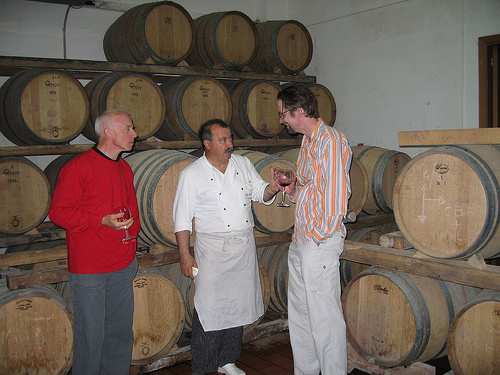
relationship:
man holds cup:
[46, 112, 146, 371] [108, 199, 137, 246]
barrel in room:
[102, 2, 197, 68] [2, 2, 499, 368]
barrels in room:
[189, 11, 259, 73] [2, 2, 499, 368]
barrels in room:
[250, 18, 316, 73] [2, 2, 499, 368]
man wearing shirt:
[46, 112, 146, 371] [49, 149, 139, 270]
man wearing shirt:
[175, 119, 269, 374] [172, 150, 275, 231]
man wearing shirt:
[275, 82, 354, 375] [278, 125, 360, 247]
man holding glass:
[275, 82, 354, 375] [272, 160, 295, 210]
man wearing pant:
[46, 112, 146, 371] [66, 253, 138, 374]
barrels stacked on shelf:
[95, 28, 316, 77] [4, 54, 345, 153]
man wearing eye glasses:
[275, 82, 354, 375] [277, 106, 305, 119]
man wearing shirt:
[175, 119, 269, 374] [170, 151, 277, 242]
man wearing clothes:
[175, 119, 269, 374] [172, 152, 271, 331]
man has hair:
[46, 112, 146, 371] [76, 90, 116, 144]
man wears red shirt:
[46, 104, 146, 371] [48, 149, 142, 275]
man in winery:
[275, 82, 354, 375] [1, 0, 499, 374]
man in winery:
[175, 119, 269, 374] [1, 0, 499, 374]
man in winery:
[46, 112, 146, 371] [1, 0, 499, 374]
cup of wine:
[276, 164, 297, 214] [270, 166, 292, 208]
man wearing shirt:
[275, 82, 354, 375] [292, 122, 345, 237]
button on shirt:
[207, 174, 218, 184] [170, 151, 277, 242]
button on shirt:
[218, 189, 223, 199] [170, 151, 277, 242]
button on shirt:
[222, 205, 227, 211] [170, 151, 277, 242]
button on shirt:
[233, 166, 240, 177] [170, 151, 277, 242]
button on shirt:
[243, 198, 248, 208] [170, 151, 277, 242]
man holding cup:
[46, 112, 146, 371] [108, 199, 142, 249]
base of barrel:
[143, 2, 197, 62] [101, 2, 203, 74]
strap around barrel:
[209, 11, 230, 68] [185, 10, 262, 73]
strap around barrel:
[196, 4, 212, 67] [185, 10, 262, 73]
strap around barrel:
[190, 8, 203, 71] [185, 10, 262, 73]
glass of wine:
[261, 162, 328, 232] [381, 109, 499, 278]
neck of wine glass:
[279, 190, 286, 202] [275, 166, 295, 208]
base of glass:
[268, 200, 298, 207] [266, 162, 299, 209]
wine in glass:
[269, 162, 294, 191] [272, 163, 297, 211]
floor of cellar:
[139, 325, 372, 374] [3, 2, 495, 370]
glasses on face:
[276, 96, 310, 121] [271, 82, 318, 136]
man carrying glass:
[275, 82, 354, 375] [274, 167, 300, 209]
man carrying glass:
[46, 104, 146, 371] [107, 195, 148, 257]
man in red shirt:
[46, 104, 146, 371] [48, 149, 142, 275]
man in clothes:
[175, 119, 269, 374] [169, 154, 269, 319]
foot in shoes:
[206, 353, 253, 373] [184, 349, 269, 373]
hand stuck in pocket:
[296, 220, 328, 262] [291, 215, 335, 282]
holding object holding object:
[182, 259, 197, 282] [191, 267, 197, 275]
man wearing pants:
[275, 82, 354, 375] [287, 231, 344, 373]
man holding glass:
[269, 73, 360, 374] [270, 149, 315, 218]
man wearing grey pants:
[46, 112, 146, 371] [68, 260, 136, 374]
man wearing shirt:
[175, 120, 269, 374] [174, 151, 272, 236]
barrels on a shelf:
[23, 2, 345, 83] [7, 52, 355, 91]